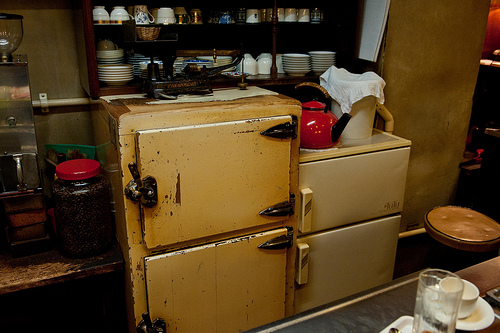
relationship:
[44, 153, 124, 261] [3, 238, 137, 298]
jar on counter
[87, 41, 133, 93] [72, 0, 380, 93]
dishes in shelf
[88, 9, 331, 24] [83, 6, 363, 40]
teacups in cupboard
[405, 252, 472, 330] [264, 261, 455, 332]
glass on counter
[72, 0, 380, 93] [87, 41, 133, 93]
shelf holds dishes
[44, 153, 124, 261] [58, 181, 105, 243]
jar full of beans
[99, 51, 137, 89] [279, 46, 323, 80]
stack of plates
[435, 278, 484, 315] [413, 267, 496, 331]
cup on saucer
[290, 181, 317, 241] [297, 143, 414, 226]
latch on freezer door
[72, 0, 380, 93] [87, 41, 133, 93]
shelves full of dishes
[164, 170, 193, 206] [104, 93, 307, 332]
rust on fridge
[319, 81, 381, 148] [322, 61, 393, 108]
container with towel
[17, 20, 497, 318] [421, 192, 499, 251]
kitchen has stool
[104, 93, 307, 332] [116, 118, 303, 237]
refrigerator has door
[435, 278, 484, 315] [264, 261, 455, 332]
cup on counter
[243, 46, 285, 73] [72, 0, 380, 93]
bowls on shelf